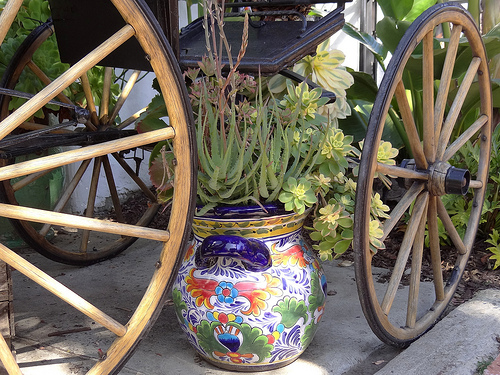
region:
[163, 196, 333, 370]
Pot of Chinese ceramic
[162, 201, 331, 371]
Pot has flower decorations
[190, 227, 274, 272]
Handle of pot is blue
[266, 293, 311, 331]
Green flower design on pot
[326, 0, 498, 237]
Leaves in a garden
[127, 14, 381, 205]
Green plant in a pot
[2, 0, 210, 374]
Wheel of a cart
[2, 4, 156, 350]
Spokes of bike are wood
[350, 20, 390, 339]
Tire is rubber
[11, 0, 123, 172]
Plant behind plant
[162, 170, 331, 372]
ornamental vase has floral pattern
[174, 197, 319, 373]
Colorful ceremic flower pot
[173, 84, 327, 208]
Aloe plant in planter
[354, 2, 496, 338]
Wheel on the right of the photograph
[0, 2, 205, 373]
Large wheel in left foreground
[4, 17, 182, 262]
Small wheel in the left background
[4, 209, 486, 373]
The cement floor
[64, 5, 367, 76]
Seat on decorative antique buggy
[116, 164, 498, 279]
The garden mulch in the background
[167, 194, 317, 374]
multi-colored flower planter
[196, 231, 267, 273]
Blue handle of colorful plenter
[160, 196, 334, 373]
Pot of a plant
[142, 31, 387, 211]
Plant in a pot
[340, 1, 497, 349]
Right wheel of a cart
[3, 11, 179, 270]
Left wheel of a cart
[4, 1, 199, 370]
Front wheel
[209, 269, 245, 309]
Blue flower decoration on a pot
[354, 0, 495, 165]
Big leaves behind a cart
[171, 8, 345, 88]
Sit of a cart is black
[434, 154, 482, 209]
Knob of a cart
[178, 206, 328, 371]
a colorful flower pot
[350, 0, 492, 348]
a large wooden wheel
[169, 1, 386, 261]
various succulent plants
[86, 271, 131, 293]
grey paved ground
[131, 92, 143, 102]
painted white wall on side of house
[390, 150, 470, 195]
large spoke of wheel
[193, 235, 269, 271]
dark blue handle of pot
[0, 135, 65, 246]
light green flower pot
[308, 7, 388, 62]
a large green leaf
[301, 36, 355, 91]
yellow and green leaves